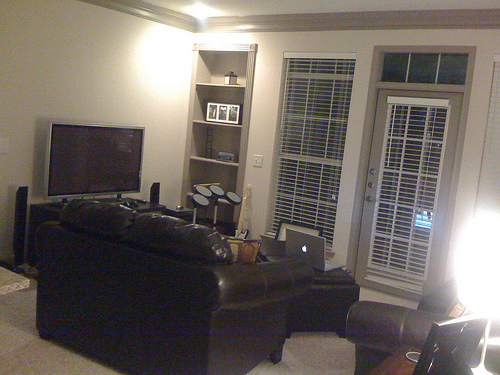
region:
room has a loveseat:
[9, 188, 314, 373]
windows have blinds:
[257, 52, 343, 235]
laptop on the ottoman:
[254, 217, 361, 325]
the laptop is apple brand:
[287, 230, 334, 275]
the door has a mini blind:
[360, 90, 445, 288]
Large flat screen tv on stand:
[19, 115, 164, 216]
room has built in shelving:
[182, 49, 250, 229]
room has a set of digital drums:
[183, 179, 248, 221]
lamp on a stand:
[360, 203, 497, 372]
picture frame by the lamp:
[397, 292, 497, 371]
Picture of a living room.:
[16, 7, 481, 373]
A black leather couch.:
[31, 182, 313, 369]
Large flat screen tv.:
[34, 107, 151, 198]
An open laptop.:
[283, 217, 339, 278]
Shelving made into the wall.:
[183, 37, 255, 220]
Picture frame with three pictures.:
[191, 95, 250, 132]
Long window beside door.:
[264, 51, 361, 258]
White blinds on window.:
[262, 46, 352, 255]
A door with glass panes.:
[351, 85, 458, 295]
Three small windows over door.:
[376, 38, 476, 93]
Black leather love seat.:
[23, 197, 316, 374]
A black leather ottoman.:
[251, 228, 363, 337]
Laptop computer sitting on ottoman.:
[281, 224, 351, 280]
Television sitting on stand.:
[28, 110, 161, 208]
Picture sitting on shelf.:
[195, 97, 249, 129]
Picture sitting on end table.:
[409, 303, 487, 372]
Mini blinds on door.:
[364, 89, 460, 291]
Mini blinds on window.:
[267, 48, 361, 260]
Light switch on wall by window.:
[248, 150, 269, 172]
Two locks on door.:
[363, 168, 378, 192]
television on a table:
[38, 110, 150, 207]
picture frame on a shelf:
[201, 96, 247, 130]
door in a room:
[343, 79, 474, 328]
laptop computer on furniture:
[279, 225, 353, 279]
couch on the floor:
[26, 186, 318, 374]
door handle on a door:
[359, 191, 379, 208]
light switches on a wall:
[245, 151, 270, 176]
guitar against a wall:
[223, 178, 265, 257]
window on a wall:
[256, 41, 368, 274]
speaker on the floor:
[7, 176, 37, 284]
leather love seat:
[28, 194, 315, 374]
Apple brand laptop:
[283, 224, 345, 276]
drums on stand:
[189, 175, 240, 222]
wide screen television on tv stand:
[46, 117, 147, 196]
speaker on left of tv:
[9, 182, 30, 274]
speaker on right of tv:
[142, 176, 166, 209]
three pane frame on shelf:
[205, 99, 242, 123]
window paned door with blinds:
[358, 81, 472, 311]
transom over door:
[366, 39, 475, 90]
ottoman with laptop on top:
[254, 230, 359, 339]